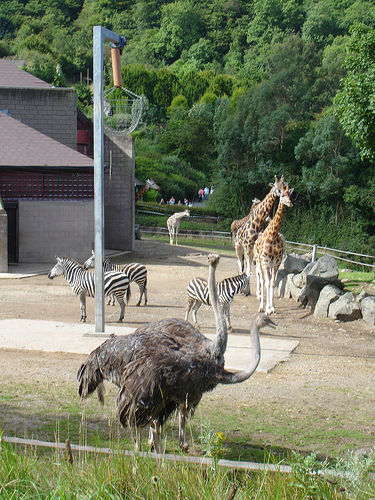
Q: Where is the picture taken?
A: A zoo.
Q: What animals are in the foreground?
A: Ostriches.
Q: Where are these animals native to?
A: Africa.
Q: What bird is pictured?
A: Ostrich.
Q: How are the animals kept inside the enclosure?
A: Fence.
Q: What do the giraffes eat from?
A: Food container.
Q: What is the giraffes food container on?
A: Pole.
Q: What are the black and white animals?
A: Zebras.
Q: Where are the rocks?
A: Next to the fence.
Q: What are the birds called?
A: Ostriches.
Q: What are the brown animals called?
A: Giraffes.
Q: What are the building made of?
A: Brick.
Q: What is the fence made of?
A: Metal.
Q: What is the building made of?
A: Stones.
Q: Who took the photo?
A: Tourist.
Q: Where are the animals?
A: Park.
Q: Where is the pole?
A: Concrete base.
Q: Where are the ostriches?
A: Forefront.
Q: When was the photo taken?
A: Sunny day.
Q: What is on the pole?
A: Basket.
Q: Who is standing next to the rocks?
A: The giraffes.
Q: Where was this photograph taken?
A: In a zoo.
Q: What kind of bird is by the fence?
A: Ostriches.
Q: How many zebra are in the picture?
A: Three.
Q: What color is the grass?
A: Green.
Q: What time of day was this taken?
A: Day time.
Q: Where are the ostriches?
A: Next to the fence.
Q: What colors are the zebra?
A: Black and white.